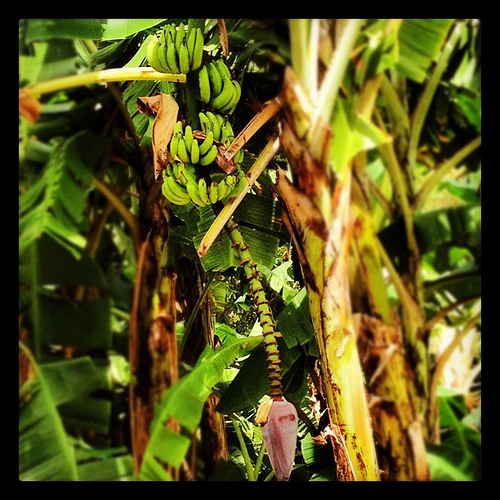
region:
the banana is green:
[190, 137, 200, 160]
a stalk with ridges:
[226, 220, 281, 396]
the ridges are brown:
[228, 221, 284, 398]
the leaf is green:
[138, 333, 260, 481]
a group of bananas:
[145, 22, 205, 69]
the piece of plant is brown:
[275, 169, 323, 286]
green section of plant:
[362, 246, 389, 321]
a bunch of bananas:
[146, 23, 241, 205]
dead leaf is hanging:
[137, 92, 176, 179]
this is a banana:
[128, 33, 225, 76]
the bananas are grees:
[143, 28, 205, 84]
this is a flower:
[248, 373, 320, 478]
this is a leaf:
[103, 310, 260, 457]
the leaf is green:
[100, 297, 267, 479]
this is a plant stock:
[247, 71, 414, 471]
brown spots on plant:
[268, 130, 338, 259]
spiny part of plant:
[223, 218, 305, 402]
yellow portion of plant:
[310, 322, 382, 478]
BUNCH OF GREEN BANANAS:
[149, 25, 203, 70]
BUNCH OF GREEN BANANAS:
[200, 109, 239, 145]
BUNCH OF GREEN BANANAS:
[161, 162, 195, 205]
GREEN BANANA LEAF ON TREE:
[43, 151, 71, 239]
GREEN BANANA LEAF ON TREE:
[18, 375, 73, 462]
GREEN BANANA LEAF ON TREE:
[157, 393, 198, 477]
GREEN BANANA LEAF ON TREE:
[51, 20, 102, 44]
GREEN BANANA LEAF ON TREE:
[296, 421, 313, 465]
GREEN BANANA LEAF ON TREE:
[456, 88, 478, 123]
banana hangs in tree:
[144, 35, 159, 70]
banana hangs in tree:
[157, 38, 167, 73]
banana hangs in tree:
[164, 42, 177, 74]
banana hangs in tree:
[178, 44, 188, 73]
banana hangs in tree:
[193, 30, 203, 69]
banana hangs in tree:
[195, 66, 210, 104]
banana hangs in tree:
[208, 63, 223, 95]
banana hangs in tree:
[213, 76, 231, 108]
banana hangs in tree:
[159, 171, 187, 206]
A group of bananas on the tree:
[136, 22, 276, 215]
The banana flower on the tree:
[251, 392, 302, 483]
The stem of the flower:
[223, 216, 293, 396]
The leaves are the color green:
[23, 136, 129, 475]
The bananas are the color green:
[143, 28, 245, 208]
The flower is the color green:
[248, 390, 305, 486]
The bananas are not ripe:
[143, 27, 248, 160]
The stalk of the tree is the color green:
[268, 22, 385, 481]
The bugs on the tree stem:
[219, 218, 290, 395]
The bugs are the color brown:
[223, 215, 287, 397]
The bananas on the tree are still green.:
[161, 165, 240, 208]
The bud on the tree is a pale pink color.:
[251, 395, 305, 479]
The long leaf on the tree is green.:
[117, 328, 242, 479]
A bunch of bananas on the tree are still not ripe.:
[144, 25, 206, 80]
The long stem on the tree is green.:
[230, 230, 294, 396]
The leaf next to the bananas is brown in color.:
[132, 93, 175, 169]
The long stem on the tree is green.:
[398, 23, 479, 167]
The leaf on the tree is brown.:
[116, 240, 173, 416]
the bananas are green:
[146, 24, 246, 205]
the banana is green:
[179, 42, 189, 74]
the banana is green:
[191, 137, 201, 165]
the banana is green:
[201, 129, 212, 154]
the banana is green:
[212, 75, 232, 110]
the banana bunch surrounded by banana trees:
[18, 19, 482, 481]